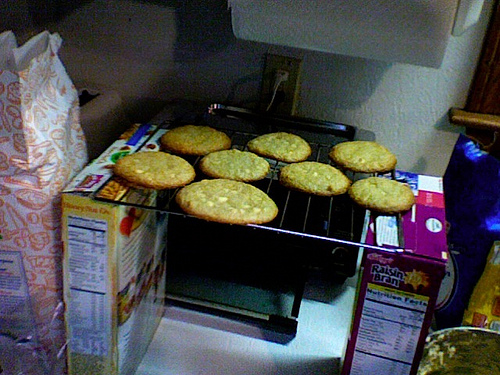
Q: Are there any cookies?
A: Yes, there is a cookie.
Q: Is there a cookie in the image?
A: Yes, there is a cookie.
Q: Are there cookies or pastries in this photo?
A: Yes, there is a cookie.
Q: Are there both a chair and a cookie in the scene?
A: No, there is a cookie but no chairs.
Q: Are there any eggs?
A: No, there are no eggs.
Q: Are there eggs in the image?
A: No, there are no eggs.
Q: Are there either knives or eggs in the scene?
A: No, there are no eggs or knives.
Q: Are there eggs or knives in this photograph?
A: No, there are no eggs or knives.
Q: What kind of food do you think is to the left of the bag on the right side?
A: The food is a cookie.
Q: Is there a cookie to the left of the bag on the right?
A: Yes, there is a cookie to the left of the bag.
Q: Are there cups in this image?
A: No, there are no cups.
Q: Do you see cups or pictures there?
A: No, there are no cups or pictures.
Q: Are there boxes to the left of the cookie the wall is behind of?
A: Yes, there is a box to the left of the cookie.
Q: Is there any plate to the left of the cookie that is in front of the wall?
A: No, there is a box to the left of the cookie.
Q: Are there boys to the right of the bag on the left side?
A: No, there is a box to the right of the bag.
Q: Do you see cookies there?
A: Yes, there is a cookie.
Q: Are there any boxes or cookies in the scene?
A: Yes, there is a cookie.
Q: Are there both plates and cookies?
A: No, there is a cookie but no plates.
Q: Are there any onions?
A: No, there are no onions.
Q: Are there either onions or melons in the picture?
A: No, there are no onions or melons.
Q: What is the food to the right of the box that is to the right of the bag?
A: The food is a cookie.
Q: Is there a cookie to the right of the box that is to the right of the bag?
A: Yes, there is a cookie to the right of the box.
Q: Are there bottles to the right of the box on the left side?
A: No, there is a cookie to the right of the box.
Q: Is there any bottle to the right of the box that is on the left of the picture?
A: No, there is a cookie to the right of the box.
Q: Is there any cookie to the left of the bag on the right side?
A: Yes, there is a cookie to the left of the bag.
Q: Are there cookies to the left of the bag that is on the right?
A: Yes, there is a cookie to the left of the bag.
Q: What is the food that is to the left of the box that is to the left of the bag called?
A: The food is a cookie.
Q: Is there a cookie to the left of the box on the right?
A: Yes, there is a cookie to the left of the box.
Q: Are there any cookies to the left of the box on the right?
A: Yes, there is a cookie to the left of the box.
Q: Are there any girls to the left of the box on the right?
A: No, there is a cookie to the left of the box.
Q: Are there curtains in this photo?
A: No, there are no curtains.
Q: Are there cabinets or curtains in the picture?
A: No, there are no curtains or cabinets.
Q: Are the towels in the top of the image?
A: Yes, the towels are in the top of the image.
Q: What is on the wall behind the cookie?
A: The towels are on the wall.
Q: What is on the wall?
A: The towels are on the wall.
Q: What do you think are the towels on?
A: The towels are on the wall.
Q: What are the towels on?
A: The towels are on the wall.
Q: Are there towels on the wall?
A: Yes, there are towels on the wall.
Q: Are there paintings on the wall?
A: No, there are towels on the wall.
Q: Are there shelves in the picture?
A: No, there are no shelves.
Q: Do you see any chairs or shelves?
A: No, there are no shelves or chairs.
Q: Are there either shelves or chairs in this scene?
A: No, there are no shelves or chairs.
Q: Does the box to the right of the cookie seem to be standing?
A: Yes, the box is standing.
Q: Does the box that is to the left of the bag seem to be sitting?
A: No, the box is standing.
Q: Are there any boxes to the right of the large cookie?
A: Yes, there is a box to the right of the cookie.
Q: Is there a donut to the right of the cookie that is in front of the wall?
A: No, there is a box to the right of the cookie.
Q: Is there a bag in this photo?
A: Yes, there is a bag.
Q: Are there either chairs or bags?
A: Yes, there is a bag.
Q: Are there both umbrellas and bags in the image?
A: No, there is a bag but no umbrellas.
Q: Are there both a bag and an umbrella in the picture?
A: No, there is a bag but no umbrellas.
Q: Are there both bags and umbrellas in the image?
A: No, there is a bag but no umbrellas.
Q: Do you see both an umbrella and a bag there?
A: No, there is a bag but no umbrellas.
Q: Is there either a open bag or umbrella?
A: Yes, there is an open bag.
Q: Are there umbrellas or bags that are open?
A: Yes, the bag is open.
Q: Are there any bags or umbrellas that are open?
A: Yes, the bag is open.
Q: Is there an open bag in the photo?
A: Yes, there is an open bag.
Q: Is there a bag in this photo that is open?
A: Yes, there is a bag that is open.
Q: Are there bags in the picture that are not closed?
A: Yes, there is a open bag.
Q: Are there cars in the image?
A: No, there are no cars.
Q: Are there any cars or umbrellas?
A: No, there are no cars or umbrellas.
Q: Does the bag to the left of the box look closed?
A: No, the bag is open.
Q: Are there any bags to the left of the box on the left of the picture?
A: Yes, there is a bag to the left of the box.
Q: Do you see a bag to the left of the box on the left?
A: Yes, there is a bag to the left of the box.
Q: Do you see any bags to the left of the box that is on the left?
A: Yes, there is a bag to the left of the box.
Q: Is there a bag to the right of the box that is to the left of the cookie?
A: No, the bag is to the left of the box.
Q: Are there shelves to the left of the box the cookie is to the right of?
A: No, there is a bag to the left of the box.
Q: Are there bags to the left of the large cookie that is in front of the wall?
A: Yes, there is a bag to the left of the cookie.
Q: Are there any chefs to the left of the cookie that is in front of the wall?
A: No, there is a bag to the left of the cookie.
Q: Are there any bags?
A: Yes, there is a bag.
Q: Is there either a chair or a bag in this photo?
A: Yes, there is a bag.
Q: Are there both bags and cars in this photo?
A: No, there is a bag but no cars.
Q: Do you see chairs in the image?
A: No, there are no chairs.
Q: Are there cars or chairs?
A: No, there are no chairs or cars.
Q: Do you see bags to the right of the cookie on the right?
A: Yes, there is a bag to the right of the cookie.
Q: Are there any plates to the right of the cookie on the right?
A: No, there is a bag to the right of the cookie.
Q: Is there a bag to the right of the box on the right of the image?
A: Yes, there is a bag to the right of the box.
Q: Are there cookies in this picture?
A: Yes, there is a cookie.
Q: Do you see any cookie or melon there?
A: Yes, there is a cookie.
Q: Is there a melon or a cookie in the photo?
A: Yes, there is a cookie.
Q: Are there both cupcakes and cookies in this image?
A: No, there is a cookie but no cupcakes.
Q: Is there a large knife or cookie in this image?
A: Yes, there is a large cookie.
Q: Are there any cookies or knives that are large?
A: Yes, the cookie is large.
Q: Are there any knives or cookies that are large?
A: Yes, the cookie is large.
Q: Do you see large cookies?
A: Yes, there is a large cookie.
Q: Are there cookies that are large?
A: Yes, there is a cookie that is large.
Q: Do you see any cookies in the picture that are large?
A: Yes, there is a cookie that is large.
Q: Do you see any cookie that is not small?
A: Yes, there is a large cookie.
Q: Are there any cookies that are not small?
A: Yes, there is a large cookie.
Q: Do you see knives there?
A: No, there are no knives.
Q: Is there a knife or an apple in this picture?
A: No, there are no knives or apples.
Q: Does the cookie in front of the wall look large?
A: Yes, the cookie is large.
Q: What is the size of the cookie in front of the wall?
A: The cookie is large.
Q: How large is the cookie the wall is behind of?
A: The cookie is large.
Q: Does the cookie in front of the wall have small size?
A: No, the cookie is large.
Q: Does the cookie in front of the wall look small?
A: No, the cookie is large.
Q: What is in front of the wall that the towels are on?
A: The cookie is in front of the wall.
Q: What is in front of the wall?
A: The cookie is in front of the wall.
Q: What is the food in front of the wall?
A: The food is a cookie.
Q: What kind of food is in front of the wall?
A: The food is a cookie.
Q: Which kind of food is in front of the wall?
A: The food is a cookie.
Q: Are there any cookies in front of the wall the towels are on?
A: Yes, there is a cookie in front of the wall.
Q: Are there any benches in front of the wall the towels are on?
A: No, there is a cookie in front of the wall.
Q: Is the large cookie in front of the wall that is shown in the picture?
A: Yes, the cookie is in front of the wall.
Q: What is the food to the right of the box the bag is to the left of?
A: The food is a cookie.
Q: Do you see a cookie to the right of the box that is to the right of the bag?
A: Yes, there is a cookie to the right of the box.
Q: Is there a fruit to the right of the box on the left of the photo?
A: No, there is a cookie to the right of the box.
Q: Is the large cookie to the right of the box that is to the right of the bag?
A: Yes, the cookie is to the right of the box.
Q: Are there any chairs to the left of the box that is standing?
A: No, there is a cookie to the left of the box.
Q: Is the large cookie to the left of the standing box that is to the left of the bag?
A: Yes, the cookie is to the left of the box.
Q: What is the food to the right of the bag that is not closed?
A: The food is a cookie.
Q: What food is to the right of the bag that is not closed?
A: The food is a cookie.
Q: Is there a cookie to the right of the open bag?
A: Yes, there is a cookie to the right of the bag.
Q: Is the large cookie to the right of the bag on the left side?
A: Yes, the cookie is to the right of the bag.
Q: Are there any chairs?
A: No, there are no chairs.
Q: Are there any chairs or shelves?
A: No, there are no chairs or shelves.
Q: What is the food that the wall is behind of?
A: The food is a cookie.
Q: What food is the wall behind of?
A: The wall is behind the cookie.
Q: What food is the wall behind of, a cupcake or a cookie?
A: The wall is behind a cookie.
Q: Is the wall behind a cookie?
A: Yes, the wall is behind a cookie.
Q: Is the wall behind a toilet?
A: No, the wall is behind a cookie.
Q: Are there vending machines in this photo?
A: No, there are no vending machines.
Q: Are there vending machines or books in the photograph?
A: No, there are no vending machines or books.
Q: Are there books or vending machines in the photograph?
A: No, there are no vending machines or books.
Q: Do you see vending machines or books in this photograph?
A: No, there are no vending machines or books.